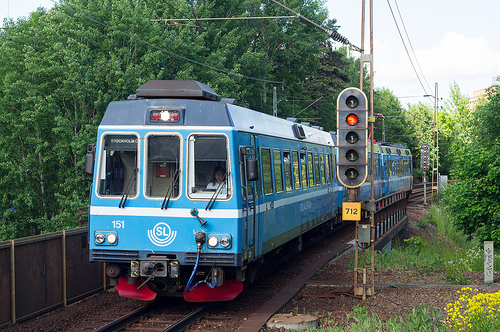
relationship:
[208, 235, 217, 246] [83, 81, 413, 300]
headlight on train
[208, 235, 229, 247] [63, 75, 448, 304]
headlight on train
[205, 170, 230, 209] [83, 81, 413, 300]
windshield wiper on train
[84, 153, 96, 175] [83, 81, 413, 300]
mirror on train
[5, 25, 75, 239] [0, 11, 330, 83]
tree in woods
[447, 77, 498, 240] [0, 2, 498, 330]
tree in woods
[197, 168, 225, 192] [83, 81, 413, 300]
person operating train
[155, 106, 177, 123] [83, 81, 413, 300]
headlight on train